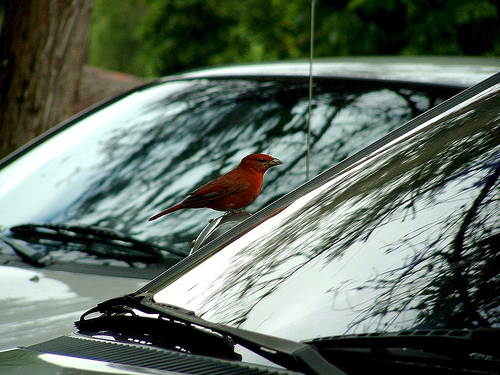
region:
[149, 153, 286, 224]
this is a red bird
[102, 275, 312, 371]
this is a wiper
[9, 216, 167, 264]
this is a wiper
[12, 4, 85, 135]
this is a tree trunk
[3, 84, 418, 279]
this is a car windscreen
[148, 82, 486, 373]
this is a car windscreen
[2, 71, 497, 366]
these are two cars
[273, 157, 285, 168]
this is a bird's beak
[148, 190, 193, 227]
this is a bird's tail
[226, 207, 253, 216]
these are a bird's legs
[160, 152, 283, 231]
red bird on car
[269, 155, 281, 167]
beak of red bird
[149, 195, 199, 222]
tail of red bird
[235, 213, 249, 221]
feet of bird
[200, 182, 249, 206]
body of bird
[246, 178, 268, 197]
chest of red bird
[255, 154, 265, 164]
eye of red bird on car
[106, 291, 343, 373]
black window wiper on car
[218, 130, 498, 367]
reflection on car window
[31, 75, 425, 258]
reflection on car window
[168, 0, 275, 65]
these are some trees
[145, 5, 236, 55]
the trees are tall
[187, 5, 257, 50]
the leaves are green in color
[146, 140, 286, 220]
this is a bird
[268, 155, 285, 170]
this is a beak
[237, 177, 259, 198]
the feathers are red in color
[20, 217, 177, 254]
this is a window wiper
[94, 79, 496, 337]
these are two windscreens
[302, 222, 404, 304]
the screen is shiny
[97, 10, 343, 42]
these are some trees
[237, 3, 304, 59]
the trees are tall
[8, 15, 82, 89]
this is a trunk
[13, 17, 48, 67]
the trunk is brown in color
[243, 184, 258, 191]
the feathers are red in color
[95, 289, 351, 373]
this is a window wiper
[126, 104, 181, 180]
this is the windscreen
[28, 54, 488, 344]
these are two cars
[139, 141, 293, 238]
bird perched on a side mirror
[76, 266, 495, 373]
a pair of windshield wipers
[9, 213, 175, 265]
windshield wipers laying on the front of the car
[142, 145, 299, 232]
orange feathers on the bird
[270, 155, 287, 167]
small pointy beak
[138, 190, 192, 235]
long feathers on the tail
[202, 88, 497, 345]
reflections on the window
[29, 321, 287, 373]
slits on the front of the car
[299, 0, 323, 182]
small antennae sticking out of the car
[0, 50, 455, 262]
large window on the front of the car